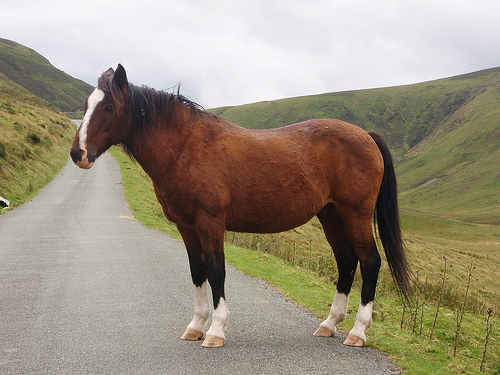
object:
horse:
[69, 63, 429, 347]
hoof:
[179, 327, 204, 341]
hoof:
[312, 324, 337, 337]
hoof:
[341, 333, 368, 346]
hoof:
[200, 334, 228, 348]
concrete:
[0, 193, 402, 375]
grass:
[398, 66, 499, 219]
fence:
[233, 233, 499, 374]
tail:
[368, 131, 425, 314]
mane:
[128, 81, 206, 164]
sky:
[0, 0, 499, 111]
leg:
[193, 210, 231, 329]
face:
[70, 71, 120, 170]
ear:
[113, 62, 127, 90]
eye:
[104, 105, 113, 113]